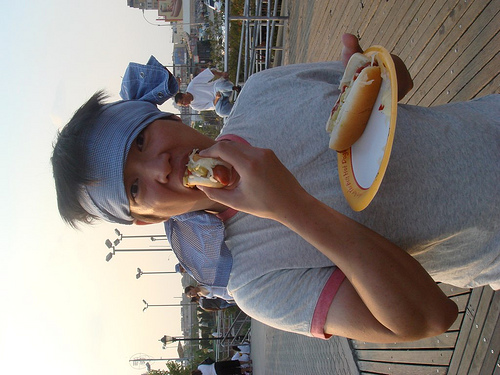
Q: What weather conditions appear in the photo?
A: It is clear.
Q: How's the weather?
A: It is clear.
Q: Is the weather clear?
A: Yes, it is clear.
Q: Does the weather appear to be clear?
A: Yes, it is clear.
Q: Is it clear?
A: Yes, it is clear.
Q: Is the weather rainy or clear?
A: It is clear.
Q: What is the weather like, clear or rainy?
A: It is clear.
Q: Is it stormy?
A: No, it is clear.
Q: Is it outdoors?
A: Yes, it is outdoors.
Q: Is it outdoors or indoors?
A: It is outdoors.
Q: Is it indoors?
A: No, it is outdoors.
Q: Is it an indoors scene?
A: No, it is outdoors.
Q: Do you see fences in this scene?
A: Yes, there is a fence.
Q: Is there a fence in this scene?
A: Yes, there is a fence.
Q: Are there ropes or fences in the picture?
A: Yes, there is a fence.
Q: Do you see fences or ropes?
A: Yes, there is a fence.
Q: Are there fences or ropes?
A: Yes, there is a fence.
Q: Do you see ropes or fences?
A: Yes, there is a fence.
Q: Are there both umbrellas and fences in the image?
A: No, there is a fence but no umbrellas.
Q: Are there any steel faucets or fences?
A: Yes, there is a steel fence.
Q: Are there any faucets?
A: No, there are no faucets.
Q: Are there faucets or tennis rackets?
A: No, there are no faucets or tennis rackets.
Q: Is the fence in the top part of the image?
A: Yes, the fence is in the top of the image.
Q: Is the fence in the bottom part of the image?
A: No, the fence is in the top of the image.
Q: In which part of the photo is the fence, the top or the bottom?
A: The fence is in the top of the image.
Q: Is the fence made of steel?
A: Yes, the fence is made of steel.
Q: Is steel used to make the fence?
A: Yes, the fence is made of steel.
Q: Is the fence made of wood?
A: No, the fence is made of steel.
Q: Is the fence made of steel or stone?
A: The fence is made of steel.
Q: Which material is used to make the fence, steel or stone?
A: The fence is made of steel.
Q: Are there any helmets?
A: No, there are no helmets.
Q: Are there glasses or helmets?
A: No, there are no helmets or glasses.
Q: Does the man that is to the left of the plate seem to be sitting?
A: Yes, the man is sitting.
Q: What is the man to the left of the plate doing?
A: The man is sitting.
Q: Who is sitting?
A: The man is sitting.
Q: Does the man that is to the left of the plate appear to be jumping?
A: No, the man is sitting.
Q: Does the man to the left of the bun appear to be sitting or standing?
A: The man is sitting.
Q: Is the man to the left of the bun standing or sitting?
A: The man is sitting.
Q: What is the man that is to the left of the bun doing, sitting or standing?
A: The man is sitting.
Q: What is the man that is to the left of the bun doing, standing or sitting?
A: The man is sitting.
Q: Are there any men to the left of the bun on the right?
A: Yes, there is a man to the left of the bun.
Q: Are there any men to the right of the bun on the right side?
A: No, the man is to the left of the bun.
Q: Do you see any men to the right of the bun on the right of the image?
A: No, the man is to the left of the bun.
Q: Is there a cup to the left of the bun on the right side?
A: No, there is a man to the left of the bun.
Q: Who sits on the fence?
A: The man sits on the fence.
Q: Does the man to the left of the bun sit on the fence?
A: Yes, the man sits on the fence.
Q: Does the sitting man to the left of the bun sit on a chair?
A: No, the man sits on the fence.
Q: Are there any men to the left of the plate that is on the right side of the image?
A: Yes, there is a man to the left of the plate.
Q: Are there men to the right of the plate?
A: No, the man is to the left of the plate.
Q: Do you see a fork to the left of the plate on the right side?
A: No, there is a man to the left of the plate.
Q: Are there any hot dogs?
A: Yes, there is a hot dog.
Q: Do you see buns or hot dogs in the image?
A: Yes, there is a hot dog.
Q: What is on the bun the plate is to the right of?
A: The hot dog is on the bun.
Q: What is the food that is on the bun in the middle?
A: The food is a hot dog.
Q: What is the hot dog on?
A: The hot dog is on the bun.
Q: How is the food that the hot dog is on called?
A: The food is a bun.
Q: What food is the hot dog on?
A: The hot dog is on the bun.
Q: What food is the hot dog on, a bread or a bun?
A: The hot dog is on a bun.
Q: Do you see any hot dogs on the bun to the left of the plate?
A: Yes, there is a hot dog on the bun.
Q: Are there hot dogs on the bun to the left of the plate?
A: Yes, there is a hot dog on the bun.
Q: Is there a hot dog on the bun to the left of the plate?
A: Yes, there is a hot dog on the bun.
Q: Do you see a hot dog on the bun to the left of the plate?
A: Yes, there is a hot dog on the bun.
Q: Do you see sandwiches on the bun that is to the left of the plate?
A: No, there is a hot dog on the bun.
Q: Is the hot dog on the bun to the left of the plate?
A: Yes, the hot dog is on the bun.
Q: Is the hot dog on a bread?
A: No, the hot dog is on the bun.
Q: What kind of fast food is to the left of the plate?
A: The food is a hot dog.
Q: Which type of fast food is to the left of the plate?
A: The food is a hot dog.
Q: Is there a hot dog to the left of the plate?
A: Yes, there is a hot dog to the left of the plate.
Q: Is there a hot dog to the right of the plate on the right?
A: No, the hot dog is to the left of the plate.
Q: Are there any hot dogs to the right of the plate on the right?
A: No, the hot dog is to the left of the plate.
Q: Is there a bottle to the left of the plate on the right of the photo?
A: No, there is a hot dog to the left of the plate.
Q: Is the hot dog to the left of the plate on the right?
A: Yes, the hot dog is to the left of the plate.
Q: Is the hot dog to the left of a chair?
A: No, the hot dog is to the left of the plate.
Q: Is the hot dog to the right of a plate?
A: No, the hot dog is to the left of a plate.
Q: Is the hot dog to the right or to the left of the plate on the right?
A: The hot dog is to the left of the plate.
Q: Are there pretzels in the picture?
A: No, there are no pretzels.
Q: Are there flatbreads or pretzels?
A: No, there are no pretzels or flatbreads.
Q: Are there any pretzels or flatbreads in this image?
A: No, there are no pretzels or flatbreads.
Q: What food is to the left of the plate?
A: The food is a bun.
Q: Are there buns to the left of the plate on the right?
A: Yes, there is a bun to the left of the plate.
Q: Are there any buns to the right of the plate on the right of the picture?
A: No, the bun is to the left of the plate.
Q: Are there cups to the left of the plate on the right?
A: No, there is a bun to the left of the plate.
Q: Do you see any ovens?
A: Yes, there is an oven.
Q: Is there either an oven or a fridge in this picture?
A: Yes, there is an oven.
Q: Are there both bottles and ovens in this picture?
A: No, there is an oven but no bottles.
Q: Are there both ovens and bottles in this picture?
A: No, there is an oven but no bottles.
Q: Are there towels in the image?
A: No, there are no towels.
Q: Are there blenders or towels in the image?
A: No, there are no towels or blenders.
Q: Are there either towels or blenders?
A: No, there are no towels or blenders.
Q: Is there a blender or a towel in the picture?
A: No, there are no towels or blenders.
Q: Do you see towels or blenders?
A: No, there are no towels or blenders.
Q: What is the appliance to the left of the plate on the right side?
A: The appliance is an oven.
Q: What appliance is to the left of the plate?
A: The appliance is an oven.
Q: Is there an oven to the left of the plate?
A: Yes, there is an oven to the left of the plate.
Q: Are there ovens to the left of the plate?
A: Yes, there is an oven to the left of the plate.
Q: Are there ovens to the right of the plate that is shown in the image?
A: No, the oven is to the left of the plate.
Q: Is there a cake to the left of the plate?
A: No, there is an oven to the left of the plate.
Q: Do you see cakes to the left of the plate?
A: No, there is an oven to the left of the plate.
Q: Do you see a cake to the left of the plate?
A: No, there is an oven to the left of the plate.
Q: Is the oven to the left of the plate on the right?
A: Yes, the oven is to the left of the plate.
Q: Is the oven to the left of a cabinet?
A: No, the oven is to the left of the plate.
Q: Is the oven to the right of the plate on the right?
A: No, the oven is to the left of the plate.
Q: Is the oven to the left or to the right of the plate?
A: The oven is to the left of the plate.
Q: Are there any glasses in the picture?
A: No, there are no glasses.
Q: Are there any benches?
A: No, there are no benches.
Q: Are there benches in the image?
A: No, there are no benches.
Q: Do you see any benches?
A: No, there are no benches.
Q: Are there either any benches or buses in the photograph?
A: No, there are no benches or buses.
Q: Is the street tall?
A: Yes, the street is tall.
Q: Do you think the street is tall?
A: Yes, the street is tall.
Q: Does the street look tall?
A: Yes, the street is tall.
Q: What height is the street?
A: The street is tall.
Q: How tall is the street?
A: The street is tall.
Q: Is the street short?
A: No, the street is tall.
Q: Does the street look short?
A: No, the street is tall.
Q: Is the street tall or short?
A: The street is tall.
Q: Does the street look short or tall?
A: The street is tall.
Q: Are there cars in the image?
A: No, there are no cars.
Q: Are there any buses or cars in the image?
A: No, there are no cars or buses.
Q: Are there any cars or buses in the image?
A: No, there are no cars or buses.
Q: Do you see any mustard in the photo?
A: Yes, there is mustard.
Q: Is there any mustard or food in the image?
A: Yes, there is mustard.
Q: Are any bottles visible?
A: No, there are no bottles.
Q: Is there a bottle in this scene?
A: No, there are no bottles.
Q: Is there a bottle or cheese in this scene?
A: No, there are no bottles or cheese.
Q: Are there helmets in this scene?
A: No, there are no helmets.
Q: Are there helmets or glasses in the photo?
A: No, there are no helmets or glasses.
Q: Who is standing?
A: The man is standing.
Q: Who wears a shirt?
A: The man wears a shirt.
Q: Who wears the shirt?
A: The man wears a shirt.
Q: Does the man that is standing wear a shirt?
A: Yes, the man wears a shirt.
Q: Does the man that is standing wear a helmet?
A: No, the man wears a shirt.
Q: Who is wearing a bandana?
A: The man is wearing a bandana.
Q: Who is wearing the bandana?
A: The man is wearing a bandana.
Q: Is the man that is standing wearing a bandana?
A: Yes, the man is wearing a bandana.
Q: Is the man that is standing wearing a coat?
A: No, the man is wearing a bandana.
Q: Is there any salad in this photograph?
A: No, there is no salad.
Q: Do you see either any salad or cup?
A: No, there are no salad or cups.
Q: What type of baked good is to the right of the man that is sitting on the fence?
A: The food is a bun.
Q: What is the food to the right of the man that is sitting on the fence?
A: The food is a bun.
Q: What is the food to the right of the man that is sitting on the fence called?
A: The food is a bun.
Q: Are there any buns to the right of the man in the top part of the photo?
A: Yes, there is a bun to the right of the man.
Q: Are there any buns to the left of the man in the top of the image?
A: No, the bun is to the right of the man.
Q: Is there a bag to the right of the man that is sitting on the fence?
A: No, there is a bun to the right of the man.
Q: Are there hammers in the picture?
A: No, there are no hammers.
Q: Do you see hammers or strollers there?
A: No, there are no hammers or strollers.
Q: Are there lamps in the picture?
A: Yes, there is a lamp.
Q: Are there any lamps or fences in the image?
A: Yes, there is a lamp.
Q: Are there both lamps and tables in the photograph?
A: No, there is a lamp but no tables.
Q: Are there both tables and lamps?
A: No, there is a lamp but no tables.